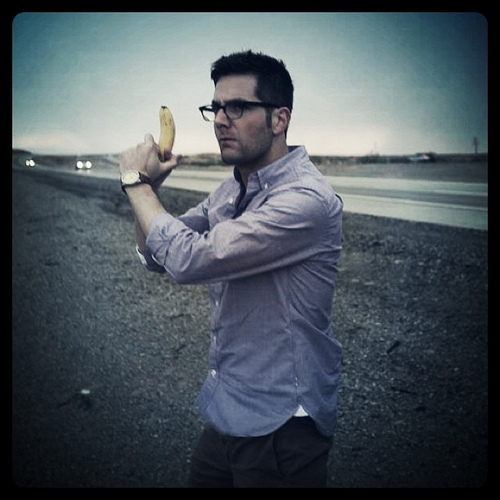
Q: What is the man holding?
A: A banana.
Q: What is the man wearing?
A: Eyeglasses.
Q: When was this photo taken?
A: In the afternoon.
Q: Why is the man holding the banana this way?
A: To be dramatic.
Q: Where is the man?
A: Next to a highway.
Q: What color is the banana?
A: Yellow.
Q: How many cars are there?
A: Two.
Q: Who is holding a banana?
A: A man wearing eyeglasses.